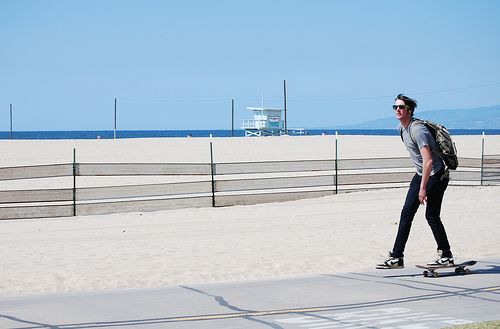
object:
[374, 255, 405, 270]
man's foot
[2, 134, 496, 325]
ground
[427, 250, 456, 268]
sneaker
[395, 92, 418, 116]
man's hair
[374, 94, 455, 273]
man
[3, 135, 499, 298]
beach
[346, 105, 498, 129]
mountains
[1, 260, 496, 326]
roadway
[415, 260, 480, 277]
skateboard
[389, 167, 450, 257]
jeans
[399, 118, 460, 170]
backpack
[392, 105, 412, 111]
sunglasses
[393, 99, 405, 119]
man's face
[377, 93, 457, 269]
guy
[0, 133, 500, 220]
fence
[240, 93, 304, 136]
lifeguard stand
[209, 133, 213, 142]
trash can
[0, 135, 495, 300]
sand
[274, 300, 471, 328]
bike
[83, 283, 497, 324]
divider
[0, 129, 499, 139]
ocean